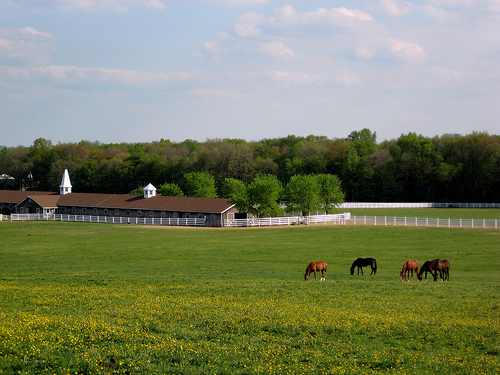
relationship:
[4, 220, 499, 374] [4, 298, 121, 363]
grass has flowers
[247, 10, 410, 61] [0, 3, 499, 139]
clouds in sky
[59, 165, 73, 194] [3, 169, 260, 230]
steeple on house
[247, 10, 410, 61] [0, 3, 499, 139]
clouds are in sky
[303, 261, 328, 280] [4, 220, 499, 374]
horse on grass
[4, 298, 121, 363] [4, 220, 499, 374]
flowers are in grass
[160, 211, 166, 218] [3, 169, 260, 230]
window on house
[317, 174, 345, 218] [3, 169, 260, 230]
tree by house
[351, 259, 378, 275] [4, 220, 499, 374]
horse on grass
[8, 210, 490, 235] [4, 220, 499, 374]
fence around grass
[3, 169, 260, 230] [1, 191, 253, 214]
house has a roof